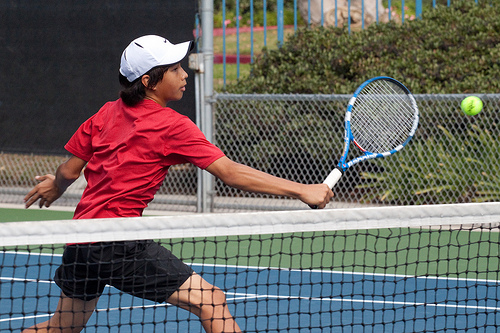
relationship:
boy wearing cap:
[23, 35, 335, 333] [118, 34, 194, 87]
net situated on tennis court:
[0, 202, 498, 333] [1, 208, 500, 331]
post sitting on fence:
[222, 1, 226, 91] [207, 92, 500, 211]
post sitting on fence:
[249, 1, 255, 71] [207, 92, 500, 211]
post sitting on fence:
[277, 0, 284, 46] [207, 92, 500, 211]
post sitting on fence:
[306, 0, 311, 26] [207, 92, 500, 211]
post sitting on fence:
[334, 1, 340, 31] [207, 92, 500, 211]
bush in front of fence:
[209, 3, 500, 198] [207, 92, 500, 211]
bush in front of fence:
[354, 122, 499, 206] [207, 92, 500, 211]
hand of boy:
[23, 175, 63, 209] [23, 35, 335, 333]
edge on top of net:
[0, 202, 499, 248] [0, 202, 498, 333]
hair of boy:
[118, 65, 169, 107] [23, 35, 335, 333]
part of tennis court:
[0, 252, 499, 332] [1, 208, 500, 331]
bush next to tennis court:
[209, 3, 500, 198] [1, 208, 500, 331]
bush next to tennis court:
[354, 122, 499, 206] [1, 208, 500, 331]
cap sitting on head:
[118, 34, 194, 87] [119, 34, 189, 102]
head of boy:
[119, 34, 189, 102] [23, 35, 335, 333]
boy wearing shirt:
[23, 35, 335, 333] [63, 98, 225, 220]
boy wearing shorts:
[23, 35, 335, 333] [54, 238, 194, 303]